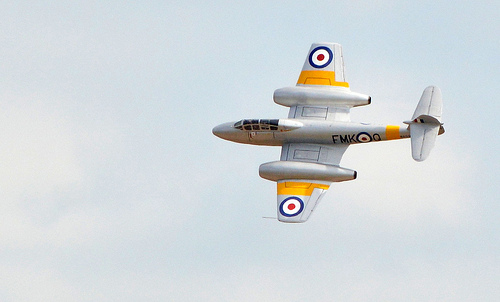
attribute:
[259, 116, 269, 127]
window — glass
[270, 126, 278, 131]
window — glass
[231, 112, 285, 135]
plane window — glass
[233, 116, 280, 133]
windows — glass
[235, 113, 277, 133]
window — glass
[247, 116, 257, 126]
window — glass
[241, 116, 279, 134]
window — glass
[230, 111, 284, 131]
window — glass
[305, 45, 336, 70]
circle — blue, white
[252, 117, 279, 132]
window — glass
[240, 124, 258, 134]
window — glass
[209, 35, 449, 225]
plane — flying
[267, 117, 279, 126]
window — glass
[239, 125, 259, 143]
window — glass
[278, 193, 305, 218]
circle — blue, white